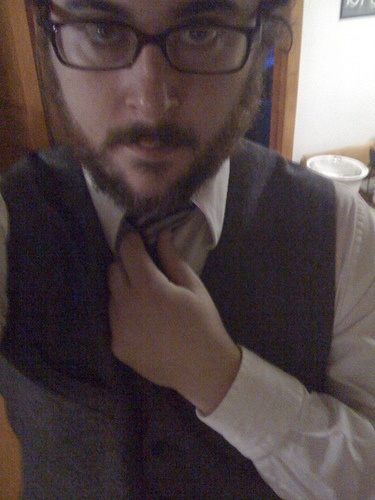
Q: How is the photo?
A: Blurry.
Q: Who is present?
A: A man.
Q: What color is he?
A: White.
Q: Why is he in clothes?
A: To keep warm.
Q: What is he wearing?
A: A tie.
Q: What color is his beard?
A: Brown.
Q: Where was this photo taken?
A: In front of a mirror.